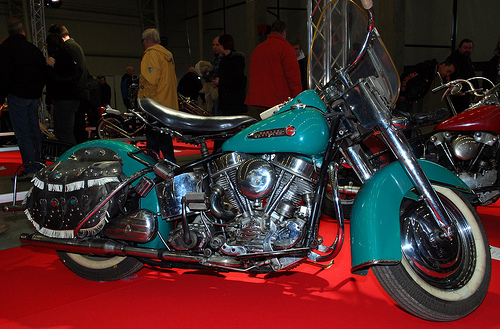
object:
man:
[243, 18, 304, 122]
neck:
[222, 51, 231, 56]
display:
[0, 0, 499, 328]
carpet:
[0, 184, 499, 328]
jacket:
[137, 43, 179, 114]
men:
[0, 19, 49, 181]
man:
[136, 28, 180, 166]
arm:
[140, 49, 160, 95]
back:
[158, 47, 177, 100]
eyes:
[209, 44, 214, 46]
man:
[211, 33, 248, 152]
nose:
[214, 48, 219, 50]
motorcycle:
[2, 1, 493, 322]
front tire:
[365, 167, 492, 323]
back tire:
[47, 139, 172, 282]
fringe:
[65, 181, 85, 193]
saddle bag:
[22, 159, 121, 238]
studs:
[65, 218, 71, 221]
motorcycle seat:
[138, 97, 260, 133]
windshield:
[310, 1, 402, 109]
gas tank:
[222, 107, 330, 158]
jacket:
[244, 33, 302, 108]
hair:
[143, 28, 161, 43]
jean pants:
[7, 94, 44, 172]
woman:
[47, 22, 90, 151]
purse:
[51, 60, 83, 82]